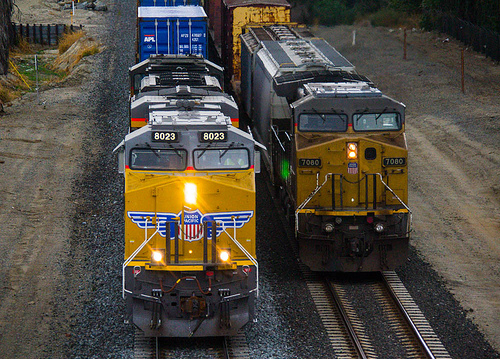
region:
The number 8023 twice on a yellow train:
[150, 128, 227, 141]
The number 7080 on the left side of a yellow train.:
[296, 155, 320, 167]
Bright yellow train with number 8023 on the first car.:
[113, 53, 263, 340]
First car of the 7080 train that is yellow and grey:
[238, 23, 410, 276]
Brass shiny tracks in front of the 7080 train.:
[318, 273, 435, 358]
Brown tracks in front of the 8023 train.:
[153, 334, 231, 356]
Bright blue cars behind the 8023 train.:
[136, 1, 208, 61]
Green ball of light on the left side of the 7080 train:
[278, 158, 291, 180]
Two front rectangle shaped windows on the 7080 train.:
[297, 110, 402, 132]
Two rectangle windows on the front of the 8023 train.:
[128, 145, 250, 170]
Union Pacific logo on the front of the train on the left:
[128, 208, 251, 243]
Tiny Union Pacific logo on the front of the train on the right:
[346, 159, 358, 174]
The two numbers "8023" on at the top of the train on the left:
[152, 128, 227, 140]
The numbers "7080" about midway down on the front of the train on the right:
[297, 155, 408, 166]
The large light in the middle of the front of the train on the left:
[184, 182, 197, 204]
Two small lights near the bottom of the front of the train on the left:
[149, 250, 232, 264]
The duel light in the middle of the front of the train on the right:
[347, 143, 356, 158]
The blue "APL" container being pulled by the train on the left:
[139, 5, 205, 61]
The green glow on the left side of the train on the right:
[278, 161, 290, 180]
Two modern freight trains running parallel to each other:
[112, 1, 411, 339]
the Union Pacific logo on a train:
[123, 207, 256, 244]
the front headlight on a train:
[162, 180, 212, 207]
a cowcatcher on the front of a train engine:
[110, 262, 262, 341]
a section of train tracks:
[311, 284, 445, 354]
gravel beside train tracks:
[72, 281, 119, 338]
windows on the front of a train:
[131, 144, 258, 179]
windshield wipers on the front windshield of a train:
[197, 142, 238, 162]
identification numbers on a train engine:
[146, 129, 232, 146]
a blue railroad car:
[128, 7, 222, 69]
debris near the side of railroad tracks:
[20, 20, 100, 102]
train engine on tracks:
[288, 86, 430, 351]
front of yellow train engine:
[117, 118, 261, 338]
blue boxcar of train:
[128, 3, 218, 64]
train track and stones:
[380, 289, 460, 352]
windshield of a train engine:
[121, 141, 259, 177]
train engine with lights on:
[118, 128, 260, 333]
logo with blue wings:
[126, 205, 253, 248]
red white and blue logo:
[123, 200, 254, 250]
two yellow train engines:
[105, 71, 412, 344]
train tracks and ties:
[293, 283, 433, 355]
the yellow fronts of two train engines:
[74, 30, 432, 346]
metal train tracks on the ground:
[313, 285, 448, 357]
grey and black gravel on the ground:
[264, 275, 321, 354]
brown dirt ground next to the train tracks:
[4, 175, 60, 312]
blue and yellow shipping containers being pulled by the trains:
[127, 0, 302, 55]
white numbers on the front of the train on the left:
[141, 125, 230, 142]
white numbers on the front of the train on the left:
[295, 154, 410, 179]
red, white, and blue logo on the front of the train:
[127, 202, 250, 250]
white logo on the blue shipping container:
[143, 31, 160, 49]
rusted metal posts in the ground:
[386, 18, 481, 111]